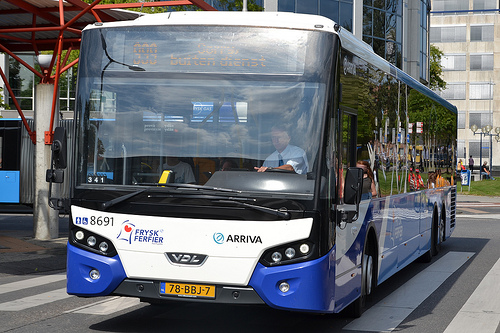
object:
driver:
[253, 122, 309, 175]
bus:
[45, 11, 457, 317]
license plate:
[163, 281, 215, 296]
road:
[0, 294, 500, 332]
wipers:
[99, 182, 243, 211]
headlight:
[88, 269, 100, 280]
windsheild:
[73, 24, 340, 210]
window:
[469, 25, 483, 42]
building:
[429, 0, 498, 176]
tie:
[277, 153, 284, 166]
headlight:
[279, 281, 290, 293]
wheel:
[345, 226, 377, 317]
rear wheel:
[430, 206, 439, 256]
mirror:
[343, 165, 365, 204]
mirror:
[50, 126, 68, 170]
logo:
[212, 232, 262, 244]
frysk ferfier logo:
[116, 219, 165, 245]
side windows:
[338, 47, 457, 199]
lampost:
[469, 123, 493, 181]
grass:
[455, 173, 500, 198]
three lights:
[75, 229, 110, 252]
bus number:
[89, 215, 115, 227]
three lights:
[270, 243, 308, 261]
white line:
[342, 250, 476, 332]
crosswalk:
[339, 248, 500, 332]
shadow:
[340, 237, 490, 332]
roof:
[81, 11, 456, 110]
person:
[157, 145, 196, 183]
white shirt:
[262, 145, 309, 174]